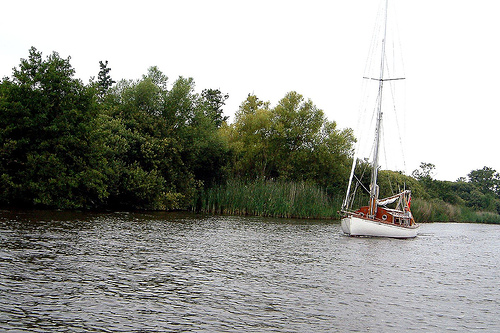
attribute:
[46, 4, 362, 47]
white sky — pure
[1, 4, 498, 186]
clear sky — white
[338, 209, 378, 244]
front — pointed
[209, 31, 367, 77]
sky — above, gray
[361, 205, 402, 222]
frames — white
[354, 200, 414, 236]
cabins — red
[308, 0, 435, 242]
boat — white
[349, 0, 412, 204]
mast — long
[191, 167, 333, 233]
grass — tall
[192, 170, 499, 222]
reeds — green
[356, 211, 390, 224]
windows — round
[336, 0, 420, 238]
boat — white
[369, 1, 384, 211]
pole — large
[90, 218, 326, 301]
water — gray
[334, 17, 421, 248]
sailboat — white, red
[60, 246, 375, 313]
lake — brown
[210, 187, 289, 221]
reeds — brown base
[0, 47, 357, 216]
trees — old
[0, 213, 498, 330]
water — river